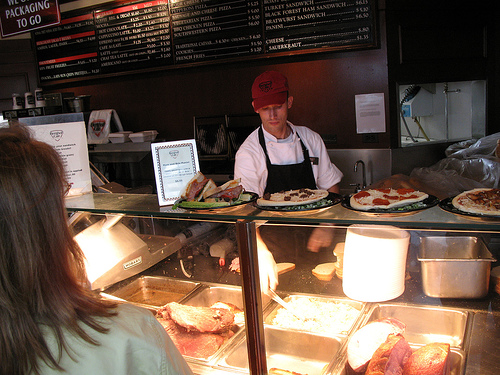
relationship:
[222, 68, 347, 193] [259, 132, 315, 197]
man wearing apron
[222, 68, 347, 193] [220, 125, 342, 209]
man wears shirt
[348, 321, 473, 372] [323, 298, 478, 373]
pieces in a container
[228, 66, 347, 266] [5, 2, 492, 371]
employee in a restaurant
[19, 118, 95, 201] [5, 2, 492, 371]
list in a restaurant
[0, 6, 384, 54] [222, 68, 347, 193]
menu above man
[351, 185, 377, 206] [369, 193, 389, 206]
pizza with slices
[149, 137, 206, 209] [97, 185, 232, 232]
paper standing on counter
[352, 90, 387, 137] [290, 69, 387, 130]
paper on wall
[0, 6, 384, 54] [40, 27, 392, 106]
menu on wall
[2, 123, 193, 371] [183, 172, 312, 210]
woman ordering food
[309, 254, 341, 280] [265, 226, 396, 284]
bread on counter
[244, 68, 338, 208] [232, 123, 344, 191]
person wearing shirt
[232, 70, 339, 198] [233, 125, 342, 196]
person wearing shirt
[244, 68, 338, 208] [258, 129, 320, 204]
person wearing apron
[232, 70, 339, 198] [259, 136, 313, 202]
person wearing apron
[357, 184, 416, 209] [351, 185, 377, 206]
pepperoni on pizza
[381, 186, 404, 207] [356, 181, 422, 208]
pepperoni on pizza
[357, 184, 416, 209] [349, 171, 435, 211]
pepperoni on pizza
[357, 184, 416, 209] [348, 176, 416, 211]
pepperoni on pizza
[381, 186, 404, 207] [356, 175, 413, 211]
pepperoni on pizza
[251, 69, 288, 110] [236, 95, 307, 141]
cap on head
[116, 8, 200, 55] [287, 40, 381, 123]
menu on wall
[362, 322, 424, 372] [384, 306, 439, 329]
meat in pan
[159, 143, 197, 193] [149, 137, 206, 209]
writing on paper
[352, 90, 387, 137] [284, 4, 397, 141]
paper on wall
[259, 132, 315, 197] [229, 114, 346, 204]
apron on shirt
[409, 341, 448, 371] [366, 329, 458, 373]
food on dish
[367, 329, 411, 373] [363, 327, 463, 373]
food on dish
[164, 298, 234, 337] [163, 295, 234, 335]
food on dish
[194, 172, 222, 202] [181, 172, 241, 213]
food on dish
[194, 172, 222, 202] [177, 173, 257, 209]
food on dish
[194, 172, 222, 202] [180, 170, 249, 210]
food on dish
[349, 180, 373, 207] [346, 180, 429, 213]
food on dish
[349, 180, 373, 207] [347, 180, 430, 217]
food on dish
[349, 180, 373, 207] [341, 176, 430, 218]
food on dish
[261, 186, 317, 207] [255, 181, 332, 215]
food on dish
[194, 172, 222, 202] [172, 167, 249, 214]
food on dish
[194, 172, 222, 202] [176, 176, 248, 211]
food on dish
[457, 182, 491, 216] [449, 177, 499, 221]
food on dish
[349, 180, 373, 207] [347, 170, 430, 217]
food on dish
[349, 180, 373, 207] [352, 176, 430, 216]
food on dish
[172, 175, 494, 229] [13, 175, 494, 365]
plates are on countertop